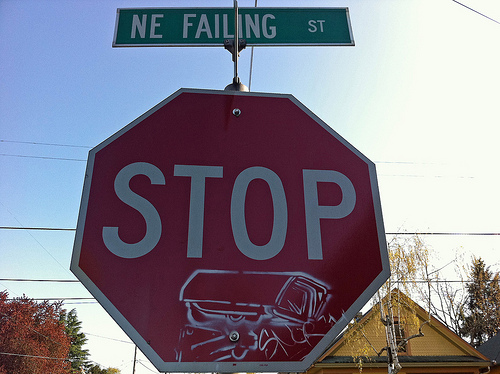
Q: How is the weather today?
A: It is sunny.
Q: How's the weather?
A: It is sunny.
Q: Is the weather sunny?
A: Yes, it is sunny.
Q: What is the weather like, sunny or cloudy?
A: It is sunny.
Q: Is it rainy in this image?
A: No, it is sunny.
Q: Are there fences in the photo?
A: No, there are no fences.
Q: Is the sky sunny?
A: Yes, the sky is sunny.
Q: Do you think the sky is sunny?
A: Yes, the sky is sunny.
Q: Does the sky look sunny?
A: Yes, the sky is sunny.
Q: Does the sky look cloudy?
A: No, the sky is sunny.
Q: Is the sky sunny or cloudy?
A: The sky is sunny.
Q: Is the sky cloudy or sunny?
A: The sky is sunny.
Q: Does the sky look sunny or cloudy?
A: The sky is sunny.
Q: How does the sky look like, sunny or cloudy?
A: The sky is sunny.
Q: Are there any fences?
A: No, there are no fences.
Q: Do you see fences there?
A: No, there are no fences.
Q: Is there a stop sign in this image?
A: Yes, there is a stop sign.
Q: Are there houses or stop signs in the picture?
A: Yes, there is a stop sign.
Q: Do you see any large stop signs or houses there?
A: Yes, there is a large stop sign.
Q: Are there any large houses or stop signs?
A: Yes, there is a large stop sign.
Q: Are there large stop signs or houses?
A: Yes, there is a large stop sign.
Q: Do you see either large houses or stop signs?
A: Yes, there is a large stop sign.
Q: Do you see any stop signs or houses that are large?
A: Yes, the stop sign is large.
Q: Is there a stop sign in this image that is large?
A: Yes, there is a large stop sign.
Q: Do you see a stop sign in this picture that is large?
A: Yes, there is a stop sign that is large.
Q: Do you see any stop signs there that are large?
A: Yes, there is a stop sign that is large.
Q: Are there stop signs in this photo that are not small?
A: Yes, there is a large stop sign.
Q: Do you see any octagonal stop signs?
A: Yes, there is an octagonal stop sign.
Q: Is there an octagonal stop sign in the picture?
A: Yes, there is an octagonal stop sign.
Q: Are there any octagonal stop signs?
A: Yes, there is an octagonal stop sign.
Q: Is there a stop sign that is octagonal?
A: Yes, there is a stop sign that is octagonal.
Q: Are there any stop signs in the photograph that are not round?
A: Yes, there is a octagonal stop sign.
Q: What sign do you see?
A: The sign is a stop sign.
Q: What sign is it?
A: The sign is a stop sign.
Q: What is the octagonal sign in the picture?
A: The sign is a stop sign.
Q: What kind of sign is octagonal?
A: The sign is a stop sign.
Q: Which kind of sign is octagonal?
A: The sign is a stop sign.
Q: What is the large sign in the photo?
A: The sign is a stop sign.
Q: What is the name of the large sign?
A: The sign is a stop sign.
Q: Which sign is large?
A: The sign is a stop sign.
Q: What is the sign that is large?
A: The sign is a stop sign.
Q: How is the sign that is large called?
A: The sign is a stop sign.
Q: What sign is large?
A: The sign is a stop sign.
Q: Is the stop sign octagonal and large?
A: Yes, the stop sign is octagonal and large.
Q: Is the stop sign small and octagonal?
A: No, the stop sign is octagonal but large.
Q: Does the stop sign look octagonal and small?
A: No, the stop sign is octagonal but large.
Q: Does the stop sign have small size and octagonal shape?
A: No, the stop sign is octagonal but large.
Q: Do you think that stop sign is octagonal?
A: Yes, the stop sign is octagonal.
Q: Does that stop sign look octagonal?
A: Yes, the stop sign is octagonal.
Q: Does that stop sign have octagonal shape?
A: Yes, the stop sign is octagonal.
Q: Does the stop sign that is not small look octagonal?
A: Yes, the stop sign is octagonal.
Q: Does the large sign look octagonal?
A: Yes, the stop sign is octagonal.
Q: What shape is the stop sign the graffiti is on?
A: The stop sign is octagonal.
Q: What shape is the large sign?
A: The stop sign is octagonal.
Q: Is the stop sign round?
A: No, the stop sign is octagonal.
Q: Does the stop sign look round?
A: No, the stop sign is octagonal.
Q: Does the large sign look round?
A: No, the stop sign is octagonal.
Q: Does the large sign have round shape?
A: No, the stop sign is octagonal.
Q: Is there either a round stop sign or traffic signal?
A: No, there is a stop sign but it is octagonal.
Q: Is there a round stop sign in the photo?
A: No, there is a stop sign but it is octagonal.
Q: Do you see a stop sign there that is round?
A: No, there is a stop sign but it is octagonal.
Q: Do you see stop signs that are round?
A: No, there is a stop sign but it is octagonal.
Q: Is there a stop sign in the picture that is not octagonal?
A: No, there is a stop sign but it is octagonal.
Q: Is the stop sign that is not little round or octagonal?
A: The stop sign is octagonal.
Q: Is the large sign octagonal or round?
A: The stop sign is octagonal.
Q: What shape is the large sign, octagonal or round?
A: The stop sign is octagonal.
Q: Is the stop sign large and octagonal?
A: Yes, the stop sign is large and octagonal.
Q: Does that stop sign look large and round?
A: No, the stop sign is large but octagonal.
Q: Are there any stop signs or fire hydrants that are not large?
A: No, there is a stop sign but it is large.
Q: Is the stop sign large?
A: Yes, the stop sign is large.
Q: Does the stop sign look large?
A: Yes, the stop sign is large.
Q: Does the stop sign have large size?
A: Yes, the stop sign is large.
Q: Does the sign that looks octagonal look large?
A: Yes, the stop sign is large.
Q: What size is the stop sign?
A: The stop sign is large.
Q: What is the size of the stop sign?
A: The stop sign is large.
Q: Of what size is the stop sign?
A: The stop sign is large.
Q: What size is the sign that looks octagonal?
A: The stop sign is large.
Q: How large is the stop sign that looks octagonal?
A: The stop sign is large.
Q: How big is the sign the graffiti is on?
A: The stop sign is large.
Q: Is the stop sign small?
A: No, the stop sign is large.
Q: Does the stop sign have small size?
A: No, the stop sign is large.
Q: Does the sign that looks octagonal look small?
A: No, the stop sign is large.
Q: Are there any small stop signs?
A: No, there is a stop sign but it is large.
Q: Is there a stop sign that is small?
A: No, there is a stop sign but it is large.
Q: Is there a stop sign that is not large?
A: No, there is a stop sign but it is large.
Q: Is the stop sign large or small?
A: The stop sign is large.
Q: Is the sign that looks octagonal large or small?
A: The stop sign is large.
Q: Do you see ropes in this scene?
A: No, there are no ropes.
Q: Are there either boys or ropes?
A: No, there are no ropes or boys.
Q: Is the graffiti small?
A: Yes, the graffiti is small.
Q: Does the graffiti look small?
A: Yes, the graffiti is small.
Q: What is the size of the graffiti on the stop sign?
A: The graffiti is small.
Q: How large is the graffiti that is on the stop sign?
A: The graffiti is small.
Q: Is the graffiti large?
A: No, the graffiti is small.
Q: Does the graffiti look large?
A: No, the graffiti is small.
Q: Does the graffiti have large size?
A: No, the graffiti is small.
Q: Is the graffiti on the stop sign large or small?
A: The graffiti is small.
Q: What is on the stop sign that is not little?
A: The graffiti is on the stop sign.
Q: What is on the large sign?
A: The graffiti is on the stop sign.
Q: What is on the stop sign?
A: The graffiti is on the stop sign.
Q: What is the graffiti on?
A: The graffiti is on the stop sign.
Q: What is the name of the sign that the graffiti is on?
A: The sign is a stop sign.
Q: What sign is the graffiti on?
A: The graffiti is on the stop sign.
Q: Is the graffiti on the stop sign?
A: Yes, the graffiti is on the stop sign.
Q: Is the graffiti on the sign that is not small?
A: Yes, the graffiti is on the stop sign.